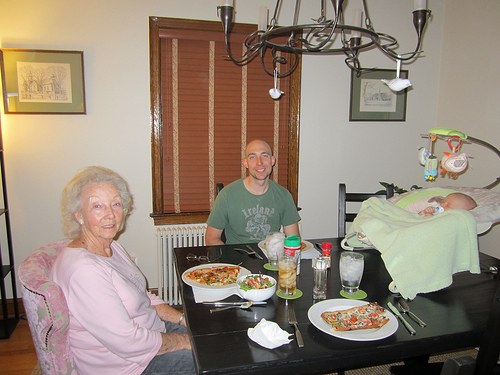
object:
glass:
[278, 255, 298, 295]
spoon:
[397, 297, 426, 327]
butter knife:
[387, 300, 415, 337]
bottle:
[281, 226, 305, 281]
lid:
[283, 233, 303, 252]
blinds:
[147, 16, 305, 217]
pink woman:
[48, 167, 198, 375]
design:
[244, 200, 284, 239]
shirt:
[206, 177, 301, 247]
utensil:
[280, 302, 306, 352]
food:
[189, 263, 240, 285]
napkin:
[244, 315, 297, 352]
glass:
[314, 255, 333, 304]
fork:
[289, 317, 307, 345]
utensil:
[232, 247, 254, 262]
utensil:
[204, 297, 276, 317]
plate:
[182, 262, 252, 292]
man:
[206, 134, 301, 251]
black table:
[165, 235, 499, 375]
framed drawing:
[347, 65, 410, 123]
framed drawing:
[2, 48, 88, 115]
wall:
[4, 0, 497, 300]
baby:
[357, 185, 477, 245]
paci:
[425, 191, 443, 204]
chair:
[340, 128, 499, 262]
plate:
[258, 235, 315, 253]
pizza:
[191, 267, 238, 283]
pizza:
[321, 302, 385, 333]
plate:
[307, 297, 402, 342]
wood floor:
[11, 334, 23, 355]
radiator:
[160, 223, 211, 309]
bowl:
[235, 272, 277, 302]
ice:
[335, 253, 363, 276]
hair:
[58, 164, 135, 239]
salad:
[245, 274, 269, 288]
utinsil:
[388, 302, 415, 337]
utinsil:
[214, 300, 253, 315]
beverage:
[276, 251, 296, 295]